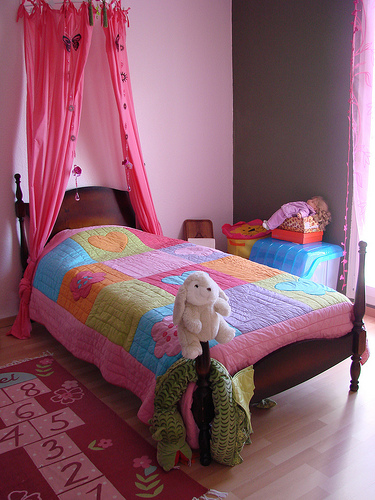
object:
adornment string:
[68, 42, 84, 200]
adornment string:
[118, 44, 134, 191]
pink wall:
[233, 1, 374, 306]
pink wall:
[0, 0, 233, 317]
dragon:
[149, 358, 251, 473]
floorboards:
[1, 324, 231, 500]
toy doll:
[260, 194, 333, 232]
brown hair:
[306, 196, 334, 231]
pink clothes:
[266, 200, 316, 232]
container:
[246, 234, 343, 292]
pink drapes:
[341, 0, 375, 306]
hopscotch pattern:
[0, 369, 130, 499]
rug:
[0, 350, 204, 499]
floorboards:
[225, 308, 375, 499]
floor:
[235, 377, 373, 499]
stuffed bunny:
[172, 270, 235, 357]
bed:
[24, 183, 370, 474]